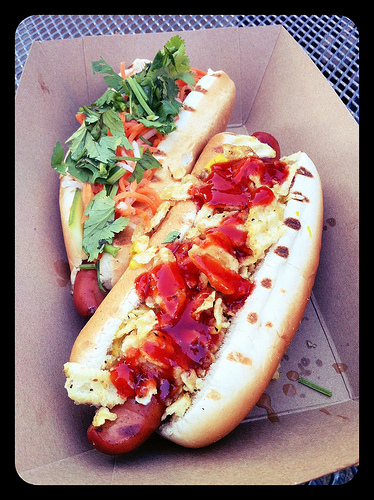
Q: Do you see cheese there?
A: No, there is no cheese.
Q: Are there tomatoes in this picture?
A: Yes, there is a tomato.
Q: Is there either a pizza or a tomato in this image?
A: Yes, there is a tomato.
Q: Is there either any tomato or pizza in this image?
A: Yes, there is a tomato.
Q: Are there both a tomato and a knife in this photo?
A: No, there is a tomato but no knives.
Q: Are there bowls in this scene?
A: No, there are no bowls.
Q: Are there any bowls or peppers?
A: No, there are no bowls or peppers.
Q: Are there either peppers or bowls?
A: No, there are no bowls or peppers.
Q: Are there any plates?
A: No, there are no plates.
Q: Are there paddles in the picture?
A: No, there are no paddles.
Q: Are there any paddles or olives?
A: No, there are no paddles or olives.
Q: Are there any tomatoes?
A: Yes, there is a tomato.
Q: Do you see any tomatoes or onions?
A: Yes, there is a tomato.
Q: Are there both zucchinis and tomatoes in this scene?
A: No, there is a tomato but no zucchinis.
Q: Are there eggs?
A: No, there are no eggs.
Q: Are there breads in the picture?
A: Yes, there is a bread.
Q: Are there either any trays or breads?
A: Yes, there is a bread.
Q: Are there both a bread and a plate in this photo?
A: No, there is a bread but no plates.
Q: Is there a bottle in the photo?
A: No, there are no bottles.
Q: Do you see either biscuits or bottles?
A: No, there are no bottles or biscuits.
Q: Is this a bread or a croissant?
A: This is a bread.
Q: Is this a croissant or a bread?
A: This is a bread.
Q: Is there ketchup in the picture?
A: Yes, there is ketchup.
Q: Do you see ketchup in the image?
A: Yes, there is ketchup.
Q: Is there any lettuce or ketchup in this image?
A: Yes, there is ketchup.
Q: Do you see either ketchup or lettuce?
A: Yes, there is ketchup.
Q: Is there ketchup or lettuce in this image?
A: Yes, there is ketchup.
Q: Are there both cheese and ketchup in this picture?
A: No, there is ketchup but no cheese.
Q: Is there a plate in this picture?
A: No, there are no plates.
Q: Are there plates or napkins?
A: No, there are no plates or napkins.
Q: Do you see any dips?
A: No, there are no dips.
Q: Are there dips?
A: No, there are no dips.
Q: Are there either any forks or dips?
A: No, there are no dips or forks.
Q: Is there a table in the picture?
A: Yes, there is a table.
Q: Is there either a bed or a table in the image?
A: Yes, there is a table.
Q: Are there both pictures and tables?
A: No, there is a table but no pictures.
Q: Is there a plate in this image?
A: No, there are no plates.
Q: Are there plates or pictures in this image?
A: No, there are no plates or pictures.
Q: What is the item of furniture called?
A: The piece of furniture is a table.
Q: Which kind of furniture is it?
A: The piece of furniture is a table.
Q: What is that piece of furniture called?
A: That is a table.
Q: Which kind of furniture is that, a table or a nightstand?
A: That is a table.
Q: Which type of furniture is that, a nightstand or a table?
A: That is a table.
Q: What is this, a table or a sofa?
A: This is a table.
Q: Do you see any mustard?
A: Yes, there is mustard.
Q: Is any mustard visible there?
A: Yes, there is mustard.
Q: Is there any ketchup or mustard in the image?
A: Yes, there is mustard.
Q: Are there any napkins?
A: No, there are no napkins.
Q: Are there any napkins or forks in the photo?
A: No, there are no napkins or forks.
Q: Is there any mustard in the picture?
A: Yes, there is mustard.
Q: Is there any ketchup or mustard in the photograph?
A: Yes, there is mustard.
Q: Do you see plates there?
A: No, there are no plates.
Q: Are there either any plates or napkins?
A: No, there are no plates or napkins.